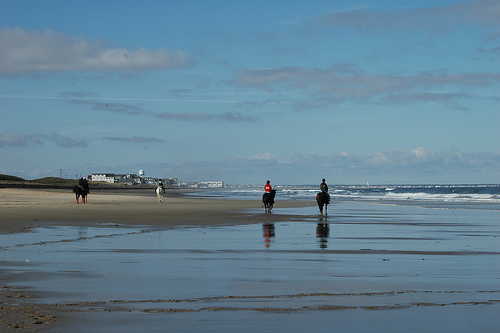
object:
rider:
[260, 179, 277, 209]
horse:
[260, 188, 277, 214]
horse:
[71, 185, 92, 205]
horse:
[315, 192, 329, 216]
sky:
[0, 21, 499, 183]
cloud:
[0, 26, 198, 75]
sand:
[107, 207, 144, 221]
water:
[423, 190, 467, 201]